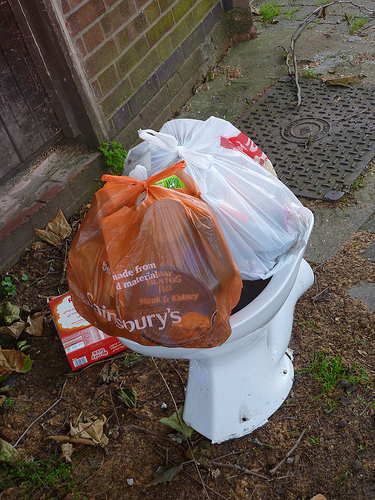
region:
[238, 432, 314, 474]
selection of brown twigs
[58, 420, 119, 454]
several crumbled brown leaves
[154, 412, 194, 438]
large green leaf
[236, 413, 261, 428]
black screw in white toilet bowl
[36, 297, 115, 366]
red and white box on ground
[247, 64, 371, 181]
large square black grate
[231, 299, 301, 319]
rim of white toilet bowl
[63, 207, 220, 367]
large orange plastic bag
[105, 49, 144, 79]
green brick on wall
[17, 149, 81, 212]
chalk covered steps on building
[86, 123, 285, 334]
Two bags of trash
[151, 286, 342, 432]
White porcelain toilet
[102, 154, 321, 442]
The trash bags are sitting in the toilet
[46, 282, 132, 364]
Box is laying on the ground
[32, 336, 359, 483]
Ground is mostly made of dirt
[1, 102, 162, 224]
Wall is made of brick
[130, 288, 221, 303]
Steak & Kidney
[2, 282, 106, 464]
Leaves lying on the ground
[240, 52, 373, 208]
Metal grate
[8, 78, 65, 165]
Door made of wood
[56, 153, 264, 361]
plastic orange bag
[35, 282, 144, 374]
empty red and white cardboard box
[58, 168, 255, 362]
orange bag filled with garbage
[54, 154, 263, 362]
plastic bag holding refuse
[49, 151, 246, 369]
orange bag holding empty containers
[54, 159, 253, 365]
orange bag holding empty can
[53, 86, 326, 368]
bags of garbage sitting on broken toilet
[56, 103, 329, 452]
white broken porcelain toilet holding bags of garbage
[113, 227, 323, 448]
broken porcelain toilet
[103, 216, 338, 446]
broken toilet sitting outside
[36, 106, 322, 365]
Two trash bags in the foreground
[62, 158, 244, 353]
Trash bag is orange in color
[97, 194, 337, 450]
Toilet seat is outside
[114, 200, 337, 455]
Toilet is white in color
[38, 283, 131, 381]
A red box in the background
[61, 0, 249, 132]
Discolored brick wall in the background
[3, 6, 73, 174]
The side of a wooden door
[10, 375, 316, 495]
Wooden sticks are on the ground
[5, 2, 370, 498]
Photo was taken in the daytime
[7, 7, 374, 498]
Photo was taken outside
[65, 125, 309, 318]
Trashbags in can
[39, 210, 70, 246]
Dead leaf in background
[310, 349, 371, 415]
Clump of green grass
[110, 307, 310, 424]
White toilet bowl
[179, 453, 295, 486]
Twigs on ground nearby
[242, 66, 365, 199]
Rubber mat behind toilet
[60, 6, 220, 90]
Brick facade behind toilet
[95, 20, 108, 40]
Line between bricks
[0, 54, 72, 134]
Door is brown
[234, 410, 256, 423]
Screw in toilet's base